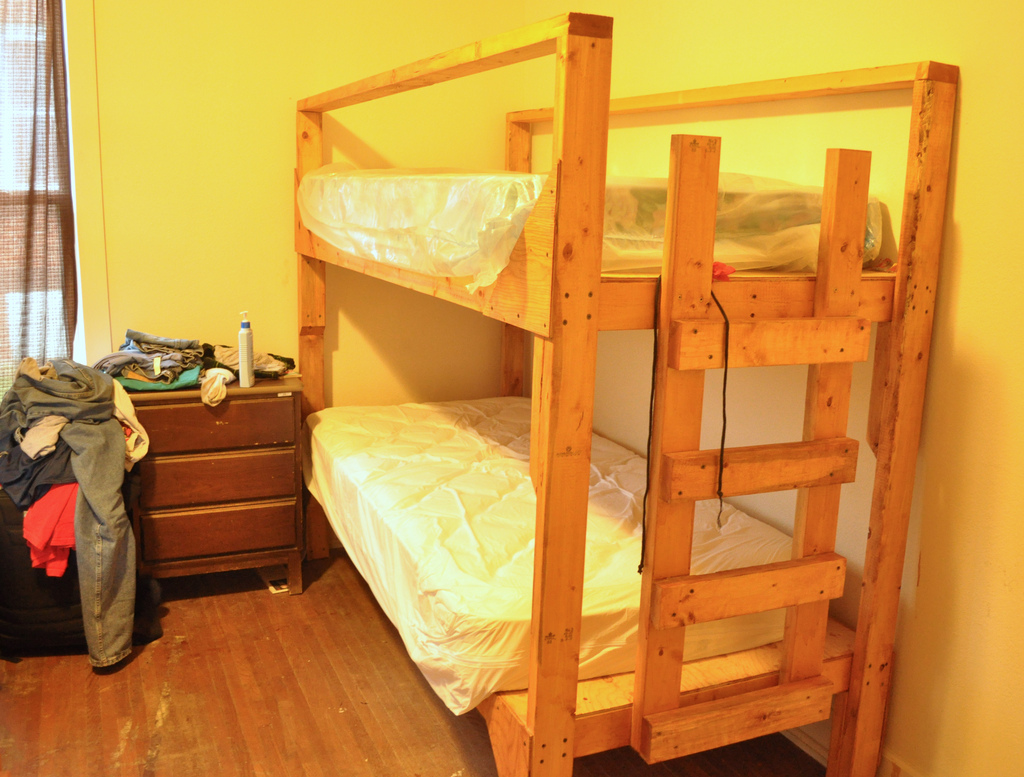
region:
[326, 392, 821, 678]
a white mattress protector on a mattress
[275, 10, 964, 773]
a bunk bed made out of two by fours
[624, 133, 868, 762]
a wooden ladder on a bunk bed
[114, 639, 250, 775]
a scuffed wooden floor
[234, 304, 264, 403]
a white and blue bottle of lotion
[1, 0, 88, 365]
brown curtains on a window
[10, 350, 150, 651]
a pile of unfolded clothing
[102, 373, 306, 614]
a small wooden dresser with three drawers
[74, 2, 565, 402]
a wall that is painted yellow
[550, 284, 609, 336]
four screws in a piece of wood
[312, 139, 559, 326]
a view of bed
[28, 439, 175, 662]
a view of pants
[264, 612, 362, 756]
a view of wood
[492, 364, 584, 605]
leg of the bed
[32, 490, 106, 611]
a view of red shirt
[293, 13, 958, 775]
bunk bed with wood frame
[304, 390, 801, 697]
box spring covered in plastic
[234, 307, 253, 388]
white bottle with pump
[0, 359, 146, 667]
pile of unfolded clothes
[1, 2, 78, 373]
material over sunlit window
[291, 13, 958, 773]
Wooden bunk beds with mattresses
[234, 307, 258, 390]
Pump top bottle of lotion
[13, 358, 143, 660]
Pile of dirty clothing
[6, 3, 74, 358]
Sheer brown window curtain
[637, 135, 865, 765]
Wooden bunk bed ladder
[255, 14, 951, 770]
Wooden bunk beds against the wall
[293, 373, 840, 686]
A mattress wrapped in white plastic.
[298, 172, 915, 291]
A mattress wrapped in clear plastic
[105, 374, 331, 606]
a brown wooden dresser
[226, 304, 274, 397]
A white and blue pump bottle.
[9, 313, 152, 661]
Clothes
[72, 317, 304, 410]
Clothes on top of the dresser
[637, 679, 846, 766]
wooden slat on bed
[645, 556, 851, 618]
wooden slat on bed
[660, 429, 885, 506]
wooden slat on bed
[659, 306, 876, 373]
wooden slat on bed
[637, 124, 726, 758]
wooden slat on bed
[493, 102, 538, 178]
wooden slat on bed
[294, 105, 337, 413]
wooden slat on bed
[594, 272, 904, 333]
wooden slat on bed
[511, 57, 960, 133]
wooden slat on bed